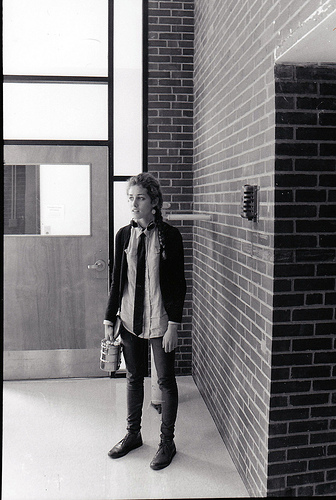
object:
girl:
[100, 170, 188, 472]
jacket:
[103, 221, 187, 323]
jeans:
[120, 322, 179, 441]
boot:
[150, 439, 178, 469]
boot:
[107, 431, 144, 459]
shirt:
[119, 221, 170, 339]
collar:
[133, 227, 142, 236]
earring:
[151, 208, 156, 216]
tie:
[133, 234, 145, 336]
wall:
[149, 3, 333, 497]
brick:
[274, 204, 321, 222]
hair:
[127, 172, 168, 262]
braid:
[156, 215, 168, 257]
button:
[145, 316, 149, 320]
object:
[97, 339, 122, 371]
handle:
[87, 262, 108, 275]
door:
[3, 145, 107, 381]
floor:
[4, 375, 250, 499]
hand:
[161, 325, 179, 353]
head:
[126, 174, 159, 220]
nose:
[132, 200, 137, 208]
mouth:
[130, 207, 142, 213]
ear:
[150, 197, 159, 211]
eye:
[127, 196, 134, 202]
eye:
[140, 197, 147, 200]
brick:
[272, 407, 312, 423]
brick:
[217, 149, 241, 159]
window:
[3, 164, 94, 237]